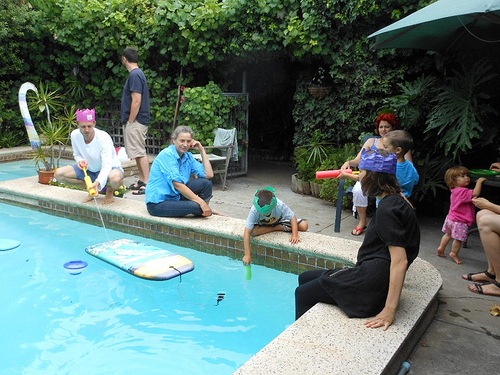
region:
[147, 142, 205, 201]
the man is wearing a blue shirt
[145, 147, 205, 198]
the man is wearing a long sleeve shirt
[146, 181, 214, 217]
the man is wearing pants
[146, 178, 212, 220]
the pants are blue in color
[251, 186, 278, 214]
the boy is wearing a hat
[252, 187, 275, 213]
the hat is green in color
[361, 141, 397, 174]
the man is wearing a hat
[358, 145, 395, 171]
the hat is blue in color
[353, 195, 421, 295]
the man is wearing short sleeve shirt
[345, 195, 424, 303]
the shirt is black in color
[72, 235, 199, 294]
small surfboard in the swimming pool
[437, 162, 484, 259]
toddler girl in pink holding on to a table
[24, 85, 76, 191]
tropical plant in a terra cotta pot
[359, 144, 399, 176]
purple paper hat on a person dressed in black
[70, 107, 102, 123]
pink paper hat on a man dressed in white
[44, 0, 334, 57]
lush green foliage near the pool area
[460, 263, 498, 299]
someone's feet wearing sandals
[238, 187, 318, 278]
young boy reaching into the pool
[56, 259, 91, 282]
blue device in the pool for adding chemicals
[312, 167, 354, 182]
red squirt gun a boy is holding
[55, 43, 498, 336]
People are sitting by a pool.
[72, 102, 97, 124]
A man is wearing a party hat.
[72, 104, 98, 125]
The colors of a party hat are pink and white.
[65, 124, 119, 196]
A man is wearing a white shirt.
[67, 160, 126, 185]
A man is wearing blue shorts.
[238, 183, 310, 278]
A child has his hand in a pool.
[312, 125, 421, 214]
A child is holding an object.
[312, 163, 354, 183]
The color of an object is red.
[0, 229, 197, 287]
Objects are floating in a pool.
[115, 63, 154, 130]
A man is wearing a dark shirt.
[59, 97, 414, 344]
people sitting by pool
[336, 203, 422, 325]
woman's shirt is black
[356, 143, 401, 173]
woman wearing a crown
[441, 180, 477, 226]
little girl's shirt is pink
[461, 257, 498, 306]
woman is wearing sandals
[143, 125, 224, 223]
woman's elbow on leg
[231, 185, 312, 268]
boy touching the water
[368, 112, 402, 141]
woman's hair is red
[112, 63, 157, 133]
man's shirt is blue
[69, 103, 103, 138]
man wearing pink crown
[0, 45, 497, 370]
People sitting on the edge of a pool.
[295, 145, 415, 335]
Teenager dressed in black.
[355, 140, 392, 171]
A purple crown on the person's head.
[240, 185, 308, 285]
A little boy holding a toy in the water.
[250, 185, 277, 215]
Boy wearing a green crown.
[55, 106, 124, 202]
A man squirting a squirt gun.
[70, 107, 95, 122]
The man is wearing a pink crown.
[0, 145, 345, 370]
A swimming pool filled with water.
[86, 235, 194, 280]
A floating toy in the water.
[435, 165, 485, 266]
A little girl dressing in pink.